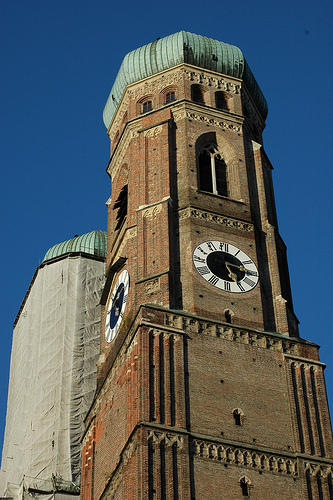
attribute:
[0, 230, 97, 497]
building — brown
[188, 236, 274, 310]
clock — old, black, white, large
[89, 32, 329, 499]
tower — tall, brown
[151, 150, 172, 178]
brick — red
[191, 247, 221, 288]
roman numerals — black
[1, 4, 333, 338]
sky — clear, blue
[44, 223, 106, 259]
top — copper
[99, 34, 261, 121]
roof — green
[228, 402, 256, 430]
window — keyhole shaped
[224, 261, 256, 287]
hands — gold, golden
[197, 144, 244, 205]
double window — large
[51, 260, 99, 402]
cover — beige